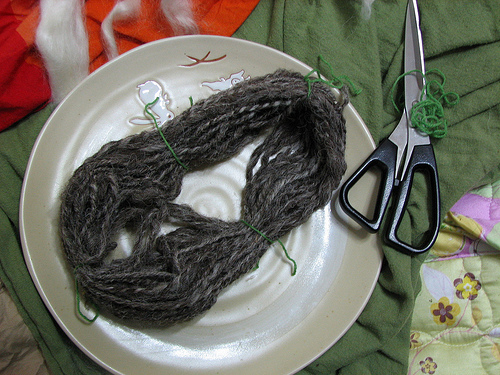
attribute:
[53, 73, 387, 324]
yarn — gray, looped, black, cut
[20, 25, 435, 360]
plate — ceramic, designed, etched, beige, round, sitting, white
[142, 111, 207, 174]
thread — thin, bound, tied, green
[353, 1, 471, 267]
scissors — black, silver, sitting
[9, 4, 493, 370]
fabric — white, yellow, green, orange, purple, flowery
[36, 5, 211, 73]
hair — white